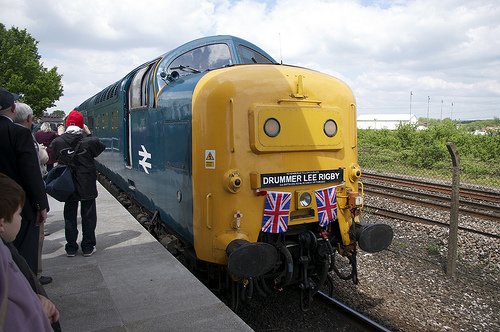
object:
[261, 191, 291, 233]
flag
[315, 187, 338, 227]
flag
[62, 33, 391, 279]
train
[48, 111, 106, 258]
man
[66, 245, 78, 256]
shoes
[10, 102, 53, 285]
man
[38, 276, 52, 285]
shoes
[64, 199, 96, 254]
pants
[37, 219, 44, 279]
pants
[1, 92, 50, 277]
man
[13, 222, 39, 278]
pants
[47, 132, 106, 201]
jacket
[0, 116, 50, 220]
jacket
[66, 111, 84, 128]
hat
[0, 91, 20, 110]
hat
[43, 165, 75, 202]
bag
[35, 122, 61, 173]
person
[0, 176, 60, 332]
person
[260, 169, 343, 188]
name sign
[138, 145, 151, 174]
logo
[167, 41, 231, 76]
window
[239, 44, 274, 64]
window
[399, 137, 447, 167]
bushes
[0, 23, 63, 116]
tree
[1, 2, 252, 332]
side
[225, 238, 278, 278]
speaker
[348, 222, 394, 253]
speaker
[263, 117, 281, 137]
light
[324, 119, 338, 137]
light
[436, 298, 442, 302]
rock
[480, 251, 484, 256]
rock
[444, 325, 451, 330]
rock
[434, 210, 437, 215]
rock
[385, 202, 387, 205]
rock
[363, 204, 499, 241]
track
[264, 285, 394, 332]
track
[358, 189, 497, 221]
track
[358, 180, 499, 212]
track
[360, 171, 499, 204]
track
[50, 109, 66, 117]
tree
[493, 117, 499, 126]
tree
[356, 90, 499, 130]
distance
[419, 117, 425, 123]
tree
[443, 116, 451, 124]
tree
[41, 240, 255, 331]
shadow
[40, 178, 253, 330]
ground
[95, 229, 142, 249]
shadow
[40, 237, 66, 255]
shadow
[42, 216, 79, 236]
shadow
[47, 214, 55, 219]
shadow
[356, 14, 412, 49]
cloud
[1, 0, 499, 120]
sky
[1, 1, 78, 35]
cloud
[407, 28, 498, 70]
cloud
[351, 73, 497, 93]
cloud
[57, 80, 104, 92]
cloud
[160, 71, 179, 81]
horn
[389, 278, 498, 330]
gravel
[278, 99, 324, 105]
handle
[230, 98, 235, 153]
handle